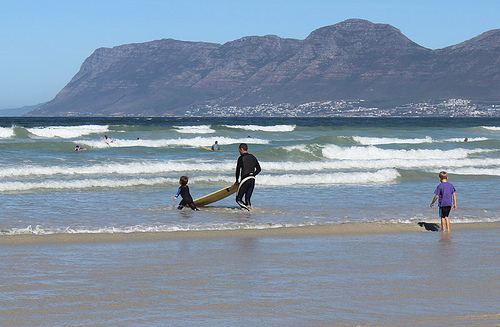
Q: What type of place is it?
A: It is a beach.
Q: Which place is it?
A: It is a beach.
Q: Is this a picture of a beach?
A: Yes, it is showing a beach.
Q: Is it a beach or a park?
A: It is a beach.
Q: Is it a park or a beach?
A: It is a beach.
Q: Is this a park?
A: No, it is a beach.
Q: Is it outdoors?
A: Yes, it is outdoors.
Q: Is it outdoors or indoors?
A: It is outdoors.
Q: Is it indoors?
A: No, it is outdoors.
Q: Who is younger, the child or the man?
A: The child is younger than the man.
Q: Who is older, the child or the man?
A: The man is older than the child.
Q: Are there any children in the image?
A: Yes, there is a child.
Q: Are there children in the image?
A: Yes, there is a child.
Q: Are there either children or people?
A: Yes, there is a child.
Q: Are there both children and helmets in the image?
A: No, there is a child but no helmets.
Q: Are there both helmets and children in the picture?
A: No, there is a child but no helmets.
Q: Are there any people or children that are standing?
A: Yes, the child is standing.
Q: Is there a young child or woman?
A: Yes, there is a young child.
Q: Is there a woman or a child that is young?
A: Yes, the child is young.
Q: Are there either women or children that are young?
A: Yes, the child is young.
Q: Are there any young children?
A: Yes, there is a young child.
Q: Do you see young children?
A: Yes, there is a young child.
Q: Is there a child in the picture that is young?
A: Yes, there is a child that is young.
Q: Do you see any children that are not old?
A: Yes, there is an young child.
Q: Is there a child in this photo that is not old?
A: Yes, there is an young child.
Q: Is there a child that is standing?
A: Yes, there is a child that is standing.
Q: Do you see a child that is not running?
A: Yes, there is a child that is standing .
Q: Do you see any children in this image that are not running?
A: Yes, there is a child that is standing .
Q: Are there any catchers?
A: No, there are no catchers.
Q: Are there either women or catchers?
A: No, there are no catchers or women.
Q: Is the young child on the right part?
A: Yes, the kid is on the right of the image.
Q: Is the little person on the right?
A: Yes, the kid is on the right of the image.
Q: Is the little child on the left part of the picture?
A: No, the child is on the right of the image.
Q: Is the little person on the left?
A: No, the child is on the right of the image.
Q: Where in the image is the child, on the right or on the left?
A: The child is on the right of the image.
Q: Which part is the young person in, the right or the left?
A: The child is on the right of the image.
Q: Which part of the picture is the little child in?
A: The kid is on the right of the image.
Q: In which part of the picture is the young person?
A: The kid is on the right of the image.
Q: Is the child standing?
A: Yes, the child is standing.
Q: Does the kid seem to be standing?
A: Yes, the kid is standing.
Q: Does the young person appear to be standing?
A: Yes, the kid is standing.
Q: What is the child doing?
A: The child is standing.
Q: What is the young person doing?
A: The child is standing.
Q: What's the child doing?
A: The child is standing.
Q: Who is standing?
A: The child is standing.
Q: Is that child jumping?
A: No, the child is standing.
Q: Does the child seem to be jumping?
A: No, the child is standing.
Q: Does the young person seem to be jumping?
A: No, the child is standing.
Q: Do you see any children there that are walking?
A: No, there is a child but he is standing.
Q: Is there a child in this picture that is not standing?
A: No, there is a child but he is standing.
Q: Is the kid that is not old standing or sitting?
A: The child is standing.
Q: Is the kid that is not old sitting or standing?
A: The child is standing.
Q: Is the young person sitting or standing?
A: The child is standing.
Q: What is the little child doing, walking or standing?
A: The kid is standing.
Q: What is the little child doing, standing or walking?
A: The kid is standing.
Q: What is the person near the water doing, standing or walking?
A: The kid is standing.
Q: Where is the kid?
A: The kid is on the beach.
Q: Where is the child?
A: The kid is on the beach.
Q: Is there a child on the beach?
A: Yes, there is a child on the beach.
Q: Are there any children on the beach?
A: Yes, there is a child on the beach.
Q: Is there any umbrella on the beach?
A: No, there is a child on the beach.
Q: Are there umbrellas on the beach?
A: No, there is a child on the beach.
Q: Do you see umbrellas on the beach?
A: No, there is a child on the beach.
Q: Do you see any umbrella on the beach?
A: No, there is a child on the beach.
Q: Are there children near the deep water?
A: Yes, there is a child near the water.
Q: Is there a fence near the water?
A: No, there is a child near the water.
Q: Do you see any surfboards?
A: Yes, there is a surfboard.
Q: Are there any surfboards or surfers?
A: Yes, there is a surfboard.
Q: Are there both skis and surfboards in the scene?
A: No, there is a surfboard but no skis.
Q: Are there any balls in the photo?
A: No, there are no balls.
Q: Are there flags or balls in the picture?
A: No, there are no balls or flags.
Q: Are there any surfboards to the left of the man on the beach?
A: Yes, there is a surfboard to the left of the man.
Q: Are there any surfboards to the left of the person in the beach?
A: Yes, there is a surfboard to the left of the man.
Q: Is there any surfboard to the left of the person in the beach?
A: Yes, there is a surfboard to the left of the man.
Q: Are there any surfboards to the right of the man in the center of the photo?
A: No, the surfboard is to the left of the man.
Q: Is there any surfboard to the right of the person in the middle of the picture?
A: No, the surfboard is to the left of the man.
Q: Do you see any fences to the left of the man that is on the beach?
A: No, there is a surfboard to the left of the man.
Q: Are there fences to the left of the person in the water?
A: No, there is a surfboard to the left of the man.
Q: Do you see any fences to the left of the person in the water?
A: No, there is a surfboard to the left of the man.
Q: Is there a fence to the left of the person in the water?
A: No, there is a surfboard to the left of the man.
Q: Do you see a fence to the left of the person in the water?
A: No, there is a surfboard to the left of the man.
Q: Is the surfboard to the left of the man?
A: Yes, the surfboard is to the left of the man.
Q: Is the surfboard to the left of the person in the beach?
A: Yes, the surfboard is to the left of the man.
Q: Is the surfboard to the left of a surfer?
A: No, the surfboard is to the left of the man.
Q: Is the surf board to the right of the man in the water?
A: No, the surf board is to the left of the man.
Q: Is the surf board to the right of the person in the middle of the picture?
A: No, the surf board is to the left of the man.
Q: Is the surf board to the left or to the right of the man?
A: The surf board is to the left of the man.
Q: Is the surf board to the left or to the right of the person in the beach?
A: The surf board is to the left of the man.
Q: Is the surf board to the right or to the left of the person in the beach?
A: The surf board is to the left of the man.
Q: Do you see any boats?
A: No, there are no boats.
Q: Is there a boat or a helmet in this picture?
A: No, there are no boats or helmets.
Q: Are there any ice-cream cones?
A: No, there are no ice-cream cones.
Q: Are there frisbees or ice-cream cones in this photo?
A: No, there are no ice-cream cones or frisbees.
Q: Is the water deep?
A: Yes, the water is deep.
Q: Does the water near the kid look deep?
A: Yes, the water is deep.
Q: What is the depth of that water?
A: The water is deep.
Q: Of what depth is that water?
A: The water is deep.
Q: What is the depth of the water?
A: The water is deep.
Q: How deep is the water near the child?
A: The water is deep.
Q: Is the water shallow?
A: No, the water is deep.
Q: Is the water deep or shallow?
A: The water is deep.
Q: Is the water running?
A: Yes, the water is running.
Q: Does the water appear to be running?
A: Yes, the water is running.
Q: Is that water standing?
A: No, the water is running.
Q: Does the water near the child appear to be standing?
A: No, the water is running.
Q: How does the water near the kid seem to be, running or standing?
A: The water is running.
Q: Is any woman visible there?
A: No, there are no women.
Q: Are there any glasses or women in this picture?
A: No, there are no women or glasses.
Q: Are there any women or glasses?
A: No, there are no women or glasses.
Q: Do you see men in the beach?
A: Yes, there is a man in the beach.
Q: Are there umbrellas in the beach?
A: No, there is a man in the beach.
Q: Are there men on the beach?
A: Yes, there is a man on the beach.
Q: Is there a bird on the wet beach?
A: No, there is a man on the beach.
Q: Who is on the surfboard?
A: The man is on the surfboard.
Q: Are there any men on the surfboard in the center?
A: Yes, there is a man on the surfboard.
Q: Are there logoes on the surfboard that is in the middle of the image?
A: No, there is a man on the surfboard.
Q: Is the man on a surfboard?
A: Yes, the man is on a surfboard.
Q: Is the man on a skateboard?
A: No, the man is on a surfboard.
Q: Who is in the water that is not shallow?
A: The man is in the water.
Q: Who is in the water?
A: The man is in the water.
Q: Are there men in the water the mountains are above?
A: Yes, there is a man in the water.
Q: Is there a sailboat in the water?
A: No, there is a man in the water.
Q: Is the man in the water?
A: Yes, the man is in the water.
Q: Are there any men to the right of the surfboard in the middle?
A: Yes, there is a man to the right of the surfboard.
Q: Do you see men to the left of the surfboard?
A: No, the man is to the right of the surfboard.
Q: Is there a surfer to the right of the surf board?
A: No, there is a man to the right of the surf board.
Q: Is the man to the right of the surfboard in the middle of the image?
A: Yes, the man is to the right of the surfboard.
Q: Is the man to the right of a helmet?
A: No, the man is to the right of the surfboard.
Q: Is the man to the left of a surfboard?
A: No, the man is to the right of a surfboard.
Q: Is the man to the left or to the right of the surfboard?
A: The man is to the right of the surfboard.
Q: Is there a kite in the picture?
A: No, there are no kites.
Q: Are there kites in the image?
A: No, there are no kites.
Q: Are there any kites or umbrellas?
A: No, there are no kites or umbrellas.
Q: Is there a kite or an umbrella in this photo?
A: No, there are no kites or umbrellas.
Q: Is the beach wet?
A: Yes, the beach is wet.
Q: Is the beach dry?
A: No, the beach is wet.